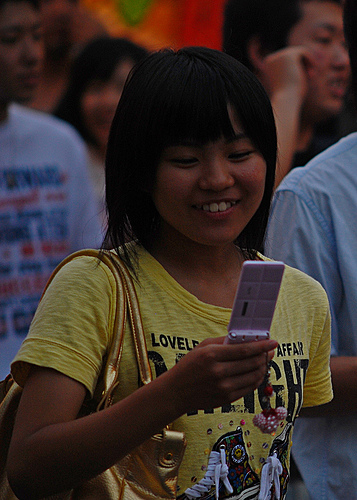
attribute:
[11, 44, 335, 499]
girl — smiling, looking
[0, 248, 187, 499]
handbag — shiny, gold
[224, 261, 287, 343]
phone — flip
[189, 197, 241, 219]
mouth — open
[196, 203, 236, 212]
teeth — white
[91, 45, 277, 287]
hair — dark black, short, black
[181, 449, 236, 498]
lace — white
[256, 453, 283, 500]
lace — white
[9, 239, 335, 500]
shirt — yellow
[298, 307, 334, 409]
sleeve — short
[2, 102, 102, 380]
shirt — white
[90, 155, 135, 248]
shirt — white